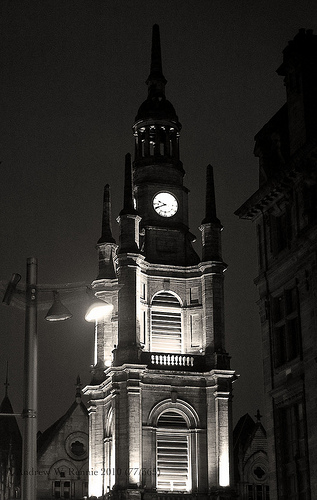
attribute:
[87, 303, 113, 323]
light — street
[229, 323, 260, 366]
sky — dark